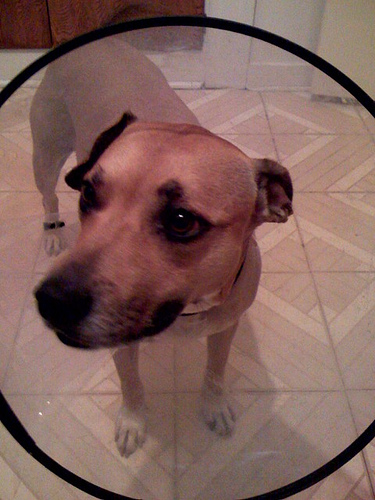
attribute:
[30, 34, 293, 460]
dog — beige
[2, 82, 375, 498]
floor — tiled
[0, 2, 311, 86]
wall — wood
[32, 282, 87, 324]
nose — black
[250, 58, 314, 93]
baseboard — white